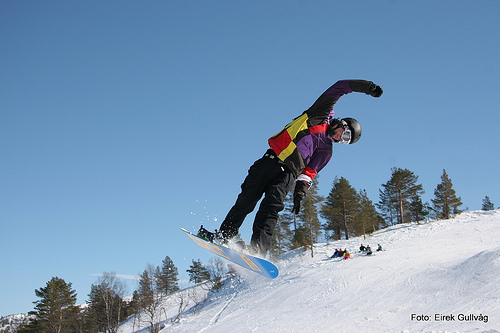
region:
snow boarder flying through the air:
[179, 44, 387, 281]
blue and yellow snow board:
[179, 224, 283, 282]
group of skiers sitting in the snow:
[326, 235, 378, 265]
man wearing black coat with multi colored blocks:
[208, 71, 388, 263]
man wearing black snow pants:
[212, 133, 293, 262]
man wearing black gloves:
[253, 73, 384, 210]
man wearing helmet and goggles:
[328, 112, 366, 152]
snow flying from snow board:
[188, 206, 282, 293]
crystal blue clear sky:
[1, 3, 498, 311]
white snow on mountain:
[90, 203, 499, 331]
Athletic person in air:
[217, 76, 387, 256]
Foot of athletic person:
[202, 226, 233, 246]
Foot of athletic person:
[245, 239, 275, 256]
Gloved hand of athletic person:
[368, 75, 388, 105]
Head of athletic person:
[333, 115, 365, 148]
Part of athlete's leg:
[262, 187, 285, 247]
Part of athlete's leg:
[232, 193, 248, 225]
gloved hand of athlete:
[292, 196, 309, 216]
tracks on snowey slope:
[312, 277, 384, 316]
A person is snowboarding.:
[177, 70, 395, 281]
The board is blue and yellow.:
[177, 221, 280, 281]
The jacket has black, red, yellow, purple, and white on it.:
[265, 60, 365, 195]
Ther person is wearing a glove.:
[370, 83, 385, 98]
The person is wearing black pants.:
[196, 150, 291, 248]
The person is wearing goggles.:
[340, 115, 350, 145]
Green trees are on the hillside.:
[320, 162, 480, 238]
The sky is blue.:
[0, 0, 226, 150]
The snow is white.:
[371, 260, 496, 295]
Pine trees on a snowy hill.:
[17, 247, 205, 329]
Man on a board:
[176, 220, 286, 280]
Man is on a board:
[179, 219, 281, 278]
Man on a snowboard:
[180, 222, 279, 281]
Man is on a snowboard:
[173, 222, 286, 286]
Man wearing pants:
[210, 147, 293, 264]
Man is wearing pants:
[215, 153, 292, 256]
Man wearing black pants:
[211, 151, 286, 252]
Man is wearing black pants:
[216, 150, 296, 260]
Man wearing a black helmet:
[342, 111, 367, 146]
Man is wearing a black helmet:
[340, 113, 364, 145]